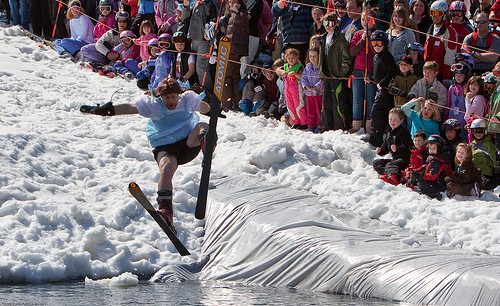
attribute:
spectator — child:
[425, 140, 444, 182]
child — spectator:
[370, 109, 406, 162]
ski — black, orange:
[123, 186, 188, 257]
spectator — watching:
[302, 53, 327, 118]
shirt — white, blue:
[154, 108, 191, 138]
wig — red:
[154, 80, 179, 93]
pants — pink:
[297, 89, 326, 128]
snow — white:
[268, 210, 364, 268]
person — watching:
[342, 44, 370, 136]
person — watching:
[161, 12, 192, 72]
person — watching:
[64, 10, 97, 60]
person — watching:
[370, 35, 385, 95]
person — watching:
[418, 70, 442, 110]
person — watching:
[448, 138, 477, 186]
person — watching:
[136, 21, 158, 58]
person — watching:
[403, 129, 434, 179]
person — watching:
[465, 120, 496, 179]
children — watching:
[190, 41, 366, 126]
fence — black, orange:
[240, 64, 355, 92]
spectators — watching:
[133, 2, 393, 131]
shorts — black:
[140, 136, 211, 166]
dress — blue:
[139, 109, 201, 143]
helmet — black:
[371, 29, 387, 42]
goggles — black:
[368, 39, 382, 47]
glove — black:
[77, 102, 112, 116]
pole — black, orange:
[359, 10, 368, 130]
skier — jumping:
[51, 57, 230, 188]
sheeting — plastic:
[175, 271, 281, 287]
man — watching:
[456, 7, 496, 72]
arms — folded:
[454, 50, 493, 62]